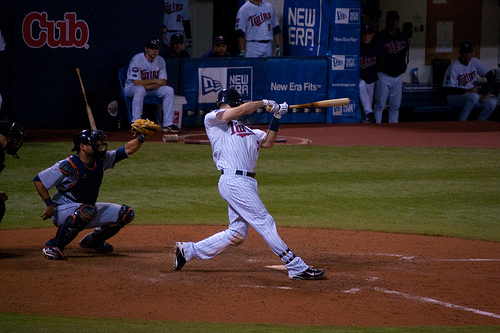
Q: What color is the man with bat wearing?
A: White.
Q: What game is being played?
A: Baseball.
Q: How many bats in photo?
A: Two.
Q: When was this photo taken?
A: Night time.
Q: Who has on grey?
A: The man to the left.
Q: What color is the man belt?
A: Black.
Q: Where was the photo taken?
A: In stadium.